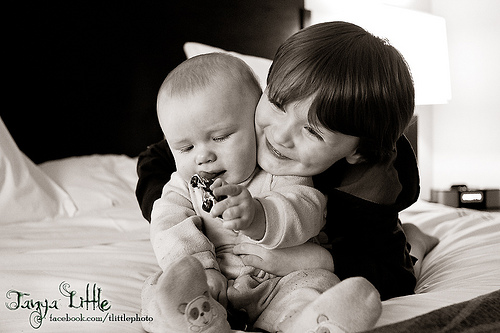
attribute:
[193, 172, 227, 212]
car — toy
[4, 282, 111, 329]
signature — professional, black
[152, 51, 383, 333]
boy — brother, sitting, smiling, barefoot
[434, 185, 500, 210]
clock — present, alarm, black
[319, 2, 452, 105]
lamp — on, in corner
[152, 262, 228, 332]
feet — panda bear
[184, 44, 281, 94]
pillow — one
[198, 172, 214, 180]
tongue — sticking out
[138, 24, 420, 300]
child — one of two, in bed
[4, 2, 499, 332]
photo — by tanya little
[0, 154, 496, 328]
sheets — white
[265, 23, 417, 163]
hair — brown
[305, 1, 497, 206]
wall — white